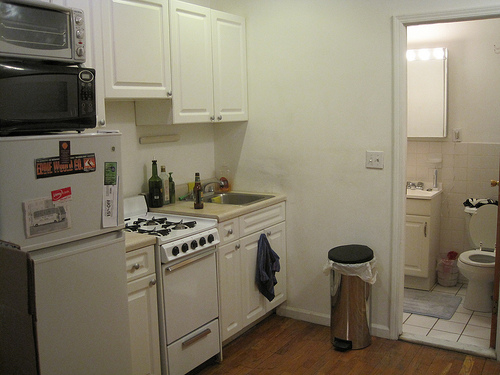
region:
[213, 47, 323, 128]
the kitchen is white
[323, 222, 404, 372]
the trashcan is chrome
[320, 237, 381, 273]
the lid of the can is black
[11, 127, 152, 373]
the refrigerator is white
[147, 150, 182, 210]
bottles are on the counter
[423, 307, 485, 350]
the floor is tile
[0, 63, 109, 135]
the micro wave is black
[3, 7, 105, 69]
the microwave is white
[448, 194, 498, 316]
the toilet is white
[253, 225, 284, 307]
the towel is black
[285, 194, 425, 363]
a trashcan with a bag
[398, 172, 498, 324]
a toilet with lid up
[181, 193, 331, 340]
a rag hanging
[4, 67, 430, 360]
kitchen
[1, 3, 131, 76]
toaster oven on top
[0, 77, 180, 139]
a black microwave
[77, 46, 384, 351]
a clean white stove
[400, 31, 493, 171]
bathroom lights are on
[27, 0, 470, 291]
a kitchen and bathroom together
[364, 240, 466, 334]
a bathroom mat in the bathroom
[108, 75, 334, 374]
A kitchen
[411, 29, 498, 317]
A bathroom.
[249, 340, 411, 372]
A wood floor.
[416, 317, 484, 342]
White floor tiles.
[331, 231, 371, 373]
A shiny metal garbage can.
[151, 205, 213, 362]
A gas oven.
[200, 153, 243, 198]
Plastic bottle of dish washing liquid.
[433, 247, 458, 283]
A garbage can with a garbage bag covering it.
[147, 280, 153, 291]
Metal handle of a cabinet.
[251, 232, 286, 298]
A dark blue drying towel.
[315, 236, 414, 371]
grey trash can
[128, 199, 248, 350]
a white stove for cooking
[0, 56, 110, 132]
a black microwave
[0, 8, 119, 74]
a white toaster oven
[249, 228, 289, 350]
towel for kitchen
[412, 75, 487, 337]
the bathroom with the door open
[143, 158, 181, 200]
a wine bottle that is open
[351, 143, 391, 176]
light switches on the wall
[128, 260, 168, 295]
handles for cuboards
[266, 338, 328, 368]
a hardwood floor for walking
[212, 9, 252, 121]
a white cupboard door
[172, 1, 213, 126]
a white cupboard door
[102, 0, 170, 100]
a white cupboard door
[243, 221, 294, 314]
a white cupboard door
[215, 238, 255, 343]
a white cupboard door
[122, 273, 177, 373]
a white cupboard door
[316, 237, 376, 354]
a silver trash can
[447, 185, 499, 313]
a white toilet seat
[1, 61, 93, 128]
a black microwave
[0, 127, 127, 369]
a white fridge